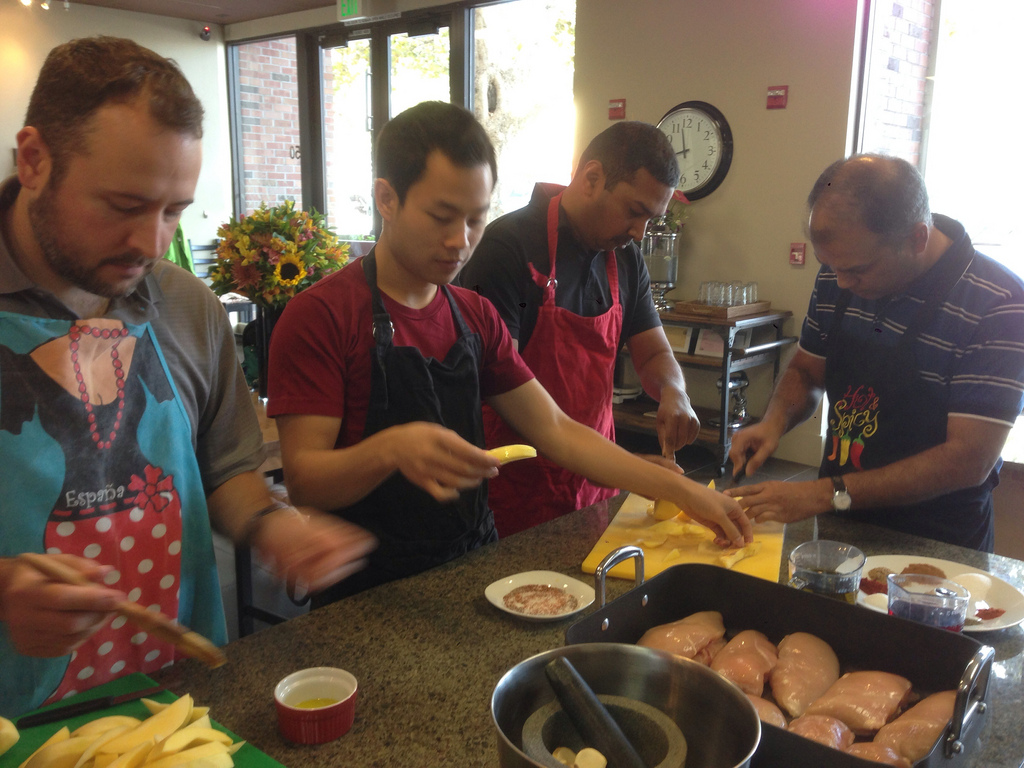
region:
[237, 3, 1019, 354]
natural light through windows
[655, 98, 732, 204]
clock with white face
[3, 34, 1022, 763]
four men preparing food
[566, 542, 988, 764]
raw meat in sqaure pan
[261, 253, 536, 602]
apron over tee shirt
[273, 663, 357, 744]
red cup with white interior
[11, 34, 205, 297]
man with bearded face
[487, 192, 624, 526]
front of red apron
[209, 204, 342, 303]
arrangment of assorted flowers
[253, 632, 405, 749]
red cup sitting on counter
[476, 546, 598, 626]
white bowl sitting on counter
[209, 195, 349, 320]
flowers in a vase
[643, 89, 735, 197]
white and black clock on wall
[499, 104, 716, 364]
man wearing a red apron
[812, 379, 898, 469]
design on front of apron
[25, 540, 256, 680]
basting brush being held by man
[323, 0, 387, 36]
green exit sign on wall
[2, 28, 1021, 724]
Men wearing aprons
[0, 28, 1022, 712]
Four men wearing aprons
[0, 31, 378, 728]
Man holding a brush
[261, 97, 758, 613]
Man wearing black apron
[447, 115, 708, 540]
Guy wearing red apron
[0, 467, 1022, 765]
Food on the counter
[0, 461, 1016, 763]
Red small bowl on the counter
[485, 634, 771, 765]
Mortar and pestle on a bowl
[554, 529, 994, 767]
pan on the counter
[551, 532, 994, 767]
pan on counter is black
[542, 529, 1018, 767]
pan full of chicken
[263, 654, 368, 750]
small bowl on counter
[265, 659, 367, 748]
small bowl is red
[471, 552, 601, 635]
small plate on counter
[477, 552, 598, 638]
small plate is white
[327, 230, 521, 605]
man wearing black apron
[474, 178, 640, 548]
man wearing red apron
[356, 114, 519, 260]
man has black hair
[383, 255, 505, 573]
man has black apron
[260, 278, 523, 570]
man has red shirt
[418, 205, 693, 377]
man has black shirt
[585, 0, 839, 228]
tan wall behind people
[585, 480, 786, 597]
wood cutting board on table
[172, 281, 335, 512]
man has grey shirt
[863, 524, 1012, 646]
white plate on table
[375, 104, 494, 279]
person has a head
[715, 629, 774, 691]
a raw piece of meat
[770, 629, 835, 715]
a raw piece of meat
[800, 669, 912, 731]
a raw piece of meat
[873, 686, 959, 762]
a raw piece of meat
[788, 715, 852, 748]
a raw piece of meat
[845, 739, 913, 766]
a raw piece of meat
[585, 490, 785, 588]
a yellow cutting board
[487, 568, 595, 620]
a small white plate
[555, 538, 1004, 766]
pan of raw chicken cutlets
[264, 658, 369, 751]
small red porcelain cup on kitchen island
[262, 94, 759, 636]
man in red t-shirt and black apron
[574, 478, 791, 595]
yellow rectangular cutting board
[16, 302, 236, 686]
apron of a woman's figurine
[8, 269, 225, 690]
apron on the man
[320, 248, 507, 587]
apron on the man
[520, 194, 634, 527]
apron on the man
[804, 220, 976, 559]
apron on the man